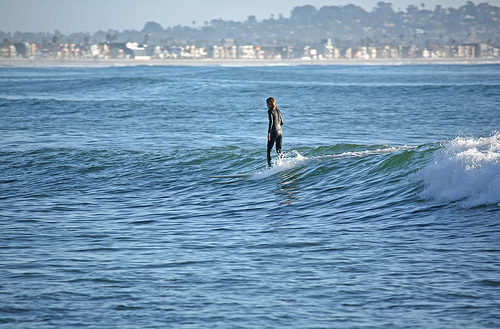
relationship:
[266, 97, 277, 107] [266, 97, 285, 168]
head of woman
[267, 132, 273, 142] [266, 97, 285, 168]
hand of woman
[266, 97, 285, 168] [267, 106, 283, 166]
woman wearing suit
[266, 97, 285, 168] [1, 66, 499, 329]
woman in water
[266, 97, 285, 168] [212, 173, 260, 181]
woman on board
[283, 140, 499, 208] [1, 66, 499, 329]
wave on water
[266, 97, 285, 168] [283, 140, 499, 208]
woman riding wave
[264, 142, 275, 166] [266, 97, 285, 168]
leg of woman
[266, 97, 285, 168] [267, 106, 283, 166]
woman in suit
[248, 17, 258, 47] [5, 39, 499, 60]
tree behind city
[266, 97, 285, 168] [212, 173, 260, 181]
woman riding board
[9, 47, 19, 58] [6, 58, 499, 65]
building on shore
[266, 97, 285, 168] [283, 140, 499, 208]
woman surfs on wave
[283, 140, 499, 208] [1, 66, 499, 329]
wave in water